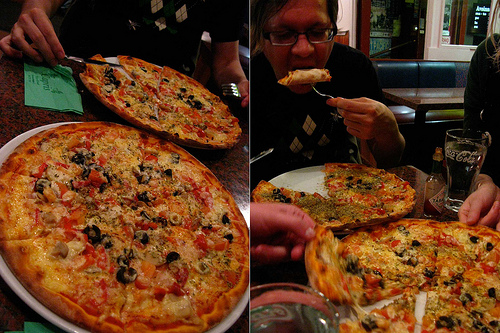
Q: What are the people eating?
A: Pizza.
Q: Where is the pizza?
A: On the table.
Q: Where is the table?
A: At a diner.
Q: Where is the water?
A: In the cup.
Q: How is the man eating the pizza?
A: With a fork.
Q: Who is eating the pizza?
A: The people.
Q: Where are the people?
A: At a diner.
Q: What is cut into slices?
A: Pizza.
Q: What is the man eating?
A: Pizza.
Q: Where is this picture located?
A: Pizzeria.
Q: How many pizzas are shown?
A: Four.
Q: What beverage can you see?
A: CocaCola.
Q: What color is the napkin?
A: Green.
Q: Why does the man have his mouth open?
A: Eat pizza.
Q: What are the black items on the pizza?
A: Olives.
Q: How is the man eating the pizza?
A: Fork.